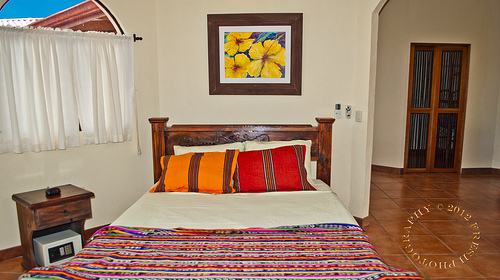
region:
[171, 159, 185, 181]
the pillow is orange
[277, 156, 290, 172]
the pillow is red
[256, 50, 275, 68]
the flower is yellow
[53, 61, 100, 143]
the curtain is cracked open some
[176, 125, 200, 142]
the headboard is brown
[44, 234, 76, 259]
the safe is white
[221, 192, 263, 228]
the bed is made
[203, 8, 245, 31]
the picture is on the wall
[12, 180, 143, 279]
a night stand standing next to a bed.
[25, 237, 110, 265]
a safe sitting in a night stand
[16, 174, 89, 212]
a remote laying on the night stand.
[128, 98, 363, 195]
4 pillows laying on the bed.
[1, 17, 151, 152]
white curtains covering a window.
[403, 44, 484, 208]
a door closed in a hallway.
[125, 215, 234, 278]
a multicolored blanket covering a bed.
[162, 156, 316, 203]
two colorful pillows laying on top of white pillows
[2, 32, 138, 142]
white curtains on the window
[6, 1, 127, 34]
a window above the curtains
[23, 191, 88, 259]
a small table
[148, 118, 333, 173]
the wooden headboard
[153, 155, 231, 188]
an orange pillow on the bed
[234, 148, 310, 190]
a red pillow on the bed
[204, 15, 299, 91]
a picture on the wall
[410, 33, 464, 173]
a door in the room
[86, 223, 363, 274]
a colorful blanket on the bed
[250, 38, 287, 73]
a yellow flower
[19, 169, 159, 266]
a night stand sitting near a bed.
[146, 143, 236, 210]
an orange pillow laying on a bed.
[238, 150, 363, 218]
a red pillow laying on a bed.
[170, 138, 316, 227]
two pillow laying on top of white pillows.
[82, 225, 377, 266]
a multicolored blanket covering a bed.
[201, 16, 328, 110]
a painting hanging on a wall.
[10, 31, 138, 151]
curtains closed on a window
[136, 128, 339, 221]
4 pillows laying on a bed.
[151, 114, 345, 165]
a wooden headboard standing behind 4 pillows.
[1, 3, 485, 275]
southwest theme bedroom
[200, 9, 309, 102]
yellow flower picture on wall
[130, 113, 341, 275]
bed with orange and red pillows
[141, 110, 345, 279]
bed with brown headboard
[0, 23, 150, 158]
white bedroom curtains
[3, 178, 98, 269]
bedside nightstand with safe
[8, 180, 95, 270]
brown bedside table with alarm clock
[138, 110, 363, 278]
multi-colored bed spread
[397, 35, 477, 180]
door with black curtains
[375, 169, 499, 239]
brown tile floor